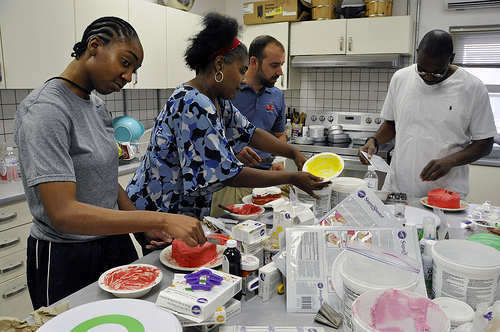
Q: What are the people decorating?
A: Cakes.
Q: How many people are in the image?
A: 4.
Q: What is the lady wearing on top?
A: A blue print top.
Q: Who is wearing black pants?
A: Lady wearing grey shirt.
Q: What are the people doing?
A: They are in the kitchen cooking.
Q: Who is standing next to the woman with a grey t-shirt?
A: The woman dressed in blue, black and white print blouse.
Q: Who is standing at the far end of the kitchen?
A: Young man dressed in white t-shirt.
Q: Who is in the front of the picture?
A: Young lady dressed in gray t-shirt.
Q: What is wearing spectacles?
A: Man wearing white shirt.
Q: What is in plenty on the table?
A: Cake supplies.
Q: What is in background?
A: White stove.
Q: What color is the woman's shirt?
A: Blue.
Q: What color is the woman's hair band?
A: Red.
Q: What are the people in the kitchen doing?
A: Baking.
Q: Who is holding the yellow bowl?
A: The woman in blue.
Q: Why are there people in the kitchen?
A: They're baking.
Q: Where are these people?
A: The kitchen.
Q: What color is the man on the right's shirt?
A: White.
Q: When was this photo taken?
A: During the day.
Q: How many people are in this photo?
A: Four.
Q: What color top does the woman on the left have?
A: Grey.